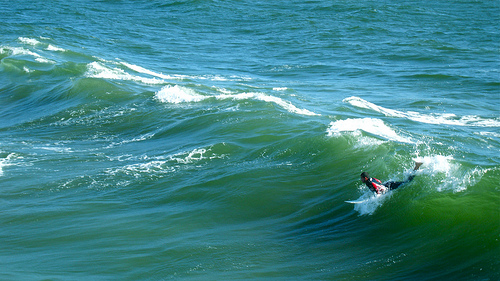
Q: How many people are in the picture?
A: One.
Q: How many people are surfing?
A: One.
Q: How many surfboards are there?
A: One.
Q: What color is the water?
A: Blue.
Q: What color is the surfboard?
A: White.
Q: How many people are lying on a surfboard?
A: One.